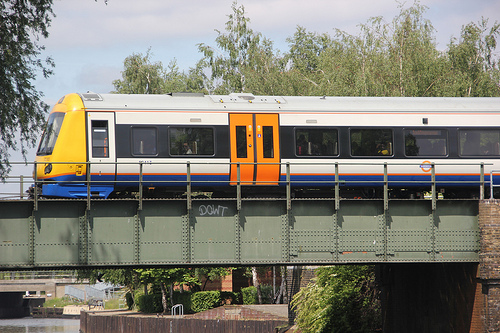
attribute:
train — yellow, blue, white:
[23, 87, 500, 198]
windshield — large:
[32, 109, 70, 158]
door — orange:
[224, 111, 284, 190]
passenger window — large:
[166, 126, 217, 159]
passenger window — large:
[293, 125, 344, 159]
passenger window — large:
[348, 126, 397, 159]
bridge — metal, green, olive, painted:
[2, 159, 500, 275]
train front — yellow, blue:
[28, 90, 92, 182]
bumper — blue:
[32, 179, 118, 201]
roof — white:
[76, 88, 500, 111]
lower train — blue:
[58, 170, 500, 189]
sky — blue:
[2, 0, 499, 198]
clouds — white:
[27, 3, 499, 59]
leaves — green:
[92, 269, 236, 288]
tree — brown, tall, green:
[155, 283, 179, 318]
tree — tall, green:
[1, 2, 60, 184]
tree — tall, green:
[110, 3, 498, 95]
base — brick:
[461, 197, 500, 331]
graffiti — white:
[192, 200, 233, 221]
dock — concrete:
[80, 297, 296, 320]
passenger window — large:
[402, 127, 451, 160]